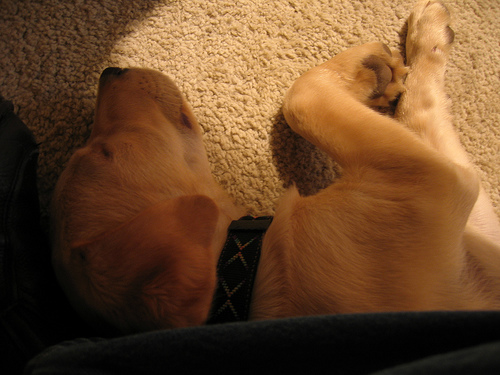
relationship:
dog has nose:
[44, 0, 493, 301] [51, 65, 231, 328]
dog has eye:
[44, 0, 493, 301] [95, 140, 116, 164]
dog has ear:
[44, 0, 493, 301] [79, 188, 222, 305]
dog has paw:
[44, 0, 493, 301] [357, 0, 464, 106]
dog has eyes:
[44, 0, 493, 301] [95, 140, 116, 164]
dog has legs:
[44, 0, 493, 301] [294, 4, 490, 199]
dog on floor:
[44, 0, 493, 301] [3, 5, 497, 196]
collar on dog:
[201, 207, 271, 333] [44, 0, 493, 301]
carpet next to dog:
[144, 0, 304, 63] [44, 0, 493, 301]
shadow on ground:
[55, 6, 148, 52] [23, 8, 292, 76]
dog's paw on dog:
[328, 41, 415, 107] [44, 0, 493, 301]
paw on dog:
[357, 0, 464, 106] [44, 0, 493, 301]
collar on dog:
[201, 207, 271, 333] [31, 0, 494, 328]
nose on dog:
[96, 62, 126, 85] [31, 0, 494, 328]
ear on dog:
[79, 188, 222, 305] [31, 0, 494, 328]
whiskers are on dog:
[66, 76, 194, 131] [31, 0, 494, 328]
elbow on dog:
[431, 150, 489, 220] [31, 0, 494, 328]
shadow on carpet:
[31, 6, 104, 60] [7, 6, 396, 103]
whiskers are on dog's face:
[133, 76, 193, 111] [39, 57, 229, 206]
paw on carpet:
[402, 0, 458, 68] [177, 5, 494, 135]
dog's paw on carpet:
[328, 41, 415, 107] [177, 5, 494, 135]